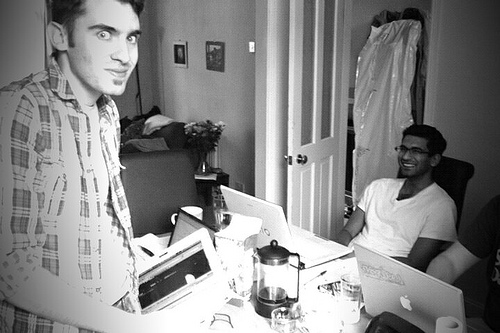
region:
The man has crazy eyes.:
[96, 29, 134, 42]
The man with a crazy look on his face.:
[0, 0, 140, 332]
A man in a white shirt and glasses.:
[333, 124, 458, 271]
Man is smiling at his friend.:
[331, 125, 457, 269]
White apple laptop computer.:
[353, 243, 465, 331]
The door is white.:
[288, 1, 352, 242]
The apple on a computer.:
[398, 293, 411, 310]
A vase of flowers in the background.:
[183, 119, 225, 174]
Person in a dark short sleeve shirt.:
[427, 191, 498, 331]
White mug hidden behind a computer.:
[171, 206, 203, 221]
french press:
[246, 236, 303, 323]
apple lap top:
[346, 237, 471, 324]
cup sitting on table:
[264, 304, 306, 329]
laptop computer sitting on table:
[221, 181, 352, 268]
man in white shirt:
[328, 121, 452, 256]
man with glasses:
[341, 116, 476, 259]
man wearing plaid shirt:
[6, 0, 192, 330]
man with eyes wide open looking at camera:
[38, 0, 155, 105]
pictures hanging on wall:
[168, 27, 234, 78]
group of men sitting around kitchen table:
[0, 3, 475, 330]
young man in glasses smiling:
[316, 125, 476, 275]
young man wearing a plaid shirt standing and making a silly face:
[8, 0, 162, 329]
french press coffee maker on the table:
[244, 234, 308, 316]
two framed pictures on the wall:
[162, 30, 235, 82]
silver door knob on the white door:
[293, 150, 312, 166]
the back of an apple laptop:
[354, 240, 475, 332]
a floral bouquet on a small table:
[182, 115, 228, 178]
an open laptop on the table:
[215, 173, 350, 267]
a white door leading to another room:
[276, 1, 353, 233]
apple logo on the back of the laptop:
[397, 296, 420, 312]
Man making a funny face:
[6, 1, 147, 331]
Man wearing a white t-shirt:
[339, 122, 461, 275]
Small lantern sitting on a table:
[248, 238, 301, 320]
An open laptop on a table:
[210, 179, 355, 276]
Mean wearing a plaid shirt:
[3, 2, 158, 330]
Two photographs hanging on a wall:
[163, 34, 230, 74]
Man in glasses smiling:
[346, 121, 461, 270]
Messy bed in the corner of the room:
[127, 105, 205, 154]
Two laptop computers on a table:
[211, 177, 471, 332]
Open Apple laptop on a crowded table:
[346, 239, 467, 331]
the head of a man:
[57, 11, 187, 113]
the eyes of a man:
[87, 8, 170, 57]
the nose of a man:
[104, 52, 150, 79]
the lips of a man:
[91, 60, 151, 102]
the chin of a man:
[83, 68, 151, 100]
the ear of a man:
[40, 0, 96, 61]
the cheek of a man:
[65, 40, 113, 104]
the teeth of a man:
[389, 157, 427, 185]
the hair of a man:
[393, 111, 464, 168]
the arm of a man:
[16, 223, 139, 330]